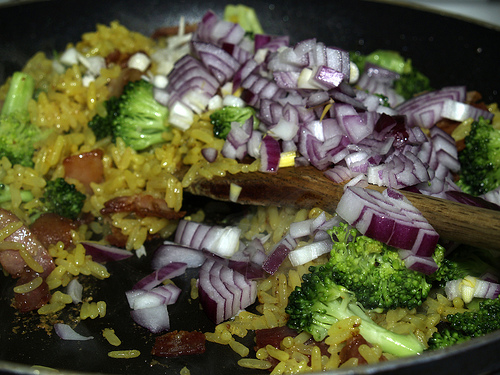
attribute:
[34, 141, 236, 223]
tomatoes — red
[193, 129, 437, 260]
spoon — wooden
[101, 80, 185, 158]
broccoli — green 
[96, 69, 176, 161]
broccoli — green 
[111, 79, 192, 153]
broccoli — small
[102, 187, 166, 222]
meat — cooked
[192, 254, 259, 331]
onion — red 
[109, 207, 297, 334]
onion — chopped up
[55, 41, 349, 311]
rice — yellow, oily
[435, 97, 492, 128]
onion — white 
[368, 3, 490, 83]
wok — black 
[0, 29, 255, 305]
rice — yellow, oily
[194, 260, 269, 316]
onion — purple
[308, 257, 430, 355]
broccoli — green, floret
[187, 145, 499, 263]
spoon — wooden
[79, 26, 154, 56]
rice — brown 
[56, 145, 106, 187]
pepper — red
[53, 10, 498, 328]
onions — purple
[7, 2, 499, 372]
wok — black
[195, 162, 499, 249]
cooking spoon — wooden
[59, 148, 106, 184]
bacon — bits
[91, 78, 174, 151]
broccoli — oily, piece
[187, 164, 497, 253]
spoon — wooden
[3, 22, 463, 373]
rice — brown, fried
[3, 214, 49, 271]
pepper — oiled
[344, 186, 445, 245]
onion — chopped, purple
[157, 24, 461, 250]
onion — red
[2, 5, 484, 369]
dish — rice, vegetable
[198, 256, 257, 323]
onion — red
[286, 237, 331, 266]
onion — red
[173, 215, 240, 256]
onion — red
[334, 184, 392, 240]
onion — red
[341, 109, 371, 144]
onion — red